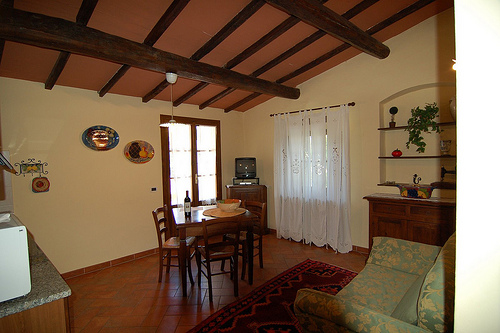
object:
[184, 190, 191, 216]
bottle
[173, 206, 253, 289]
wooden table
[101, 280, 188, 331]
tiles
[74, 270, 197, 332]
floor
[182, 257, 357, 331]
rug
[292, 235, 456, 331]
chair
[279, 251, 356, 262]
ground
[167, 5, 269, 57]
ceiling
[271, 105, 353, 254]
curtain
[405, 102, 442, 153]
plant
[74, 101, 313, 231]
wall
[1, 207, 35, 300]
microwave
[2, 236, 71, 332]
counter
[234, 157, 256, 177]
small television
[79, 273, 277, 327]
ground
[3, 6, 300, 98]
beam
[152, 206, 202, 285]
chair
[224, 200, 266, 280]
chair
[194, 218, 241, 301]
chair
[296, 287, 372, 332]
arm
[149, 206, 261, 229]
table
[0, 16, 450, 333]
room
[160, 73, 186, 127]
light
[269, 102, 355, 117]
rod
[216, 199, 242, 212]
bowl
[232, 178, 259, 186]
stand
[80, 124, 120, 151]
plate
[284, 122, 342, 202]
window